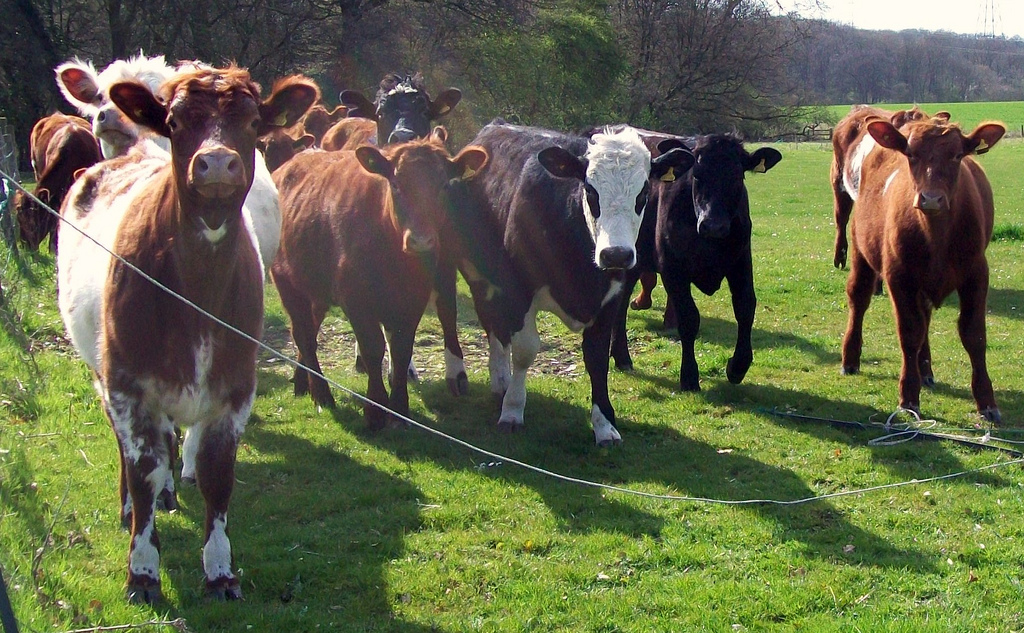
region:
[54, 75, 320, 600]
brown and white cow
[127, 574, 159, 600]
hoof of the cow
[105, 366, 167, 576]
leg of a cow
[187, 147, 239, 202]
snout of a cow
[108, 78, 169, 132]
ear of a cow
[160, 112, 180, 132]
eye of a cow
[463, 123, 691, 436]
black and white cow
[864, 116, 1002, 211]
head of a cow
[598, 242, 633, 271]
the nose is black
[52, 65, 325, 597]
a brown and white cow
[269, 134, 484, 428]
a brown and white cow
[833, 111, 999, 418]
a brown and white cow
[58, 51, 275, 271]
a large white cow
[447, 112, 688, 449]
a black and white cow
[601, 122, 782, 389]
a large black cow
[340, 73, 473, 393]
a large black cow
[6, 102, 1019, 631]
a green grassy field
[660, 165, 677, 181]
a yellow ear tag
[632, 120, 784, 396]
a solid black cow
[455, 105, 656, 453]
a black cow with white head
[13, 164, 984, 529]
a white rope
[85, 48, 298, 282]
a solid white cow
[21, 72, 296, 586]
a brown cow with white patches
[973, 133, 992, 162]
a yellow tag in ear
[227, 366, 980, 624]
shadows on ground from cows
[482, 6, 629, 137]
green leaves behind cows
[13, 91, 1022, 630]
green grass covers the ground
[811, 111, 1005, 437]
a cow in a field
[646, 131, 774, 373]
a cow in a field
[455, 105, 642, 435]
a cow in a field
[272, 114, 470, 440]
a cow in a field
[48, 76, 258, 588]
a cow in a field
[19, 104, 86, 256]
a cow in a field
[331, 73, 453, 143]
a cow in a field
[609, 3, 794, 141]
a tree in a field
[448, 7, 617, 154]
a tree in a field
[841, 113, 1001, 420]
a brown and white cow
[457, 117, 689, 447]
a black and white cow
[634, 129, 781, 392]
a large black cow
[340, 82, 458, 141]
a large black cow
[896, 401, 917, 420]
hoof of adult cow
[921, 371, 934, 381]
hoof of adult cow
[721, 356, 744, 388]
hoof of adult cow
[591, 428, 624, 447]
hoof of adult cow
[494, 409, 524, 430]
hoof of adult cow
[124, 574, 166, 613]
hoof of adult cow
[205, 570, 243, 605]
hoof of adult cow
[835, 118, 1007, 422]
dark brown cow in right side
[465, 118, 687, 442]
black and white cow in the middle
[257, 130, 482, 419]
dark brown cow between black and white cow and brown and white cow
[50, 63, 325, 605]
brown and white cow in left side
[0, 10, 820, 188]
a bunch of bushes in the background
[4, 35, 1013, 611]
cattle standing in green grass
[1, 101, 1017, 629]
green grass in the ground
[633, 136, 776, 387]
black cow standing in the ground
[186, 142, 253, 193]
big pink nose in cow in left side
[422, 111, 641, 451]
A cow in a field.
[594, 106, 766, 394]
A cow in a field.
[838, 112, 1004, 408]
A cow in a field.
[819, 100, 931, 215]
A cow in a field.